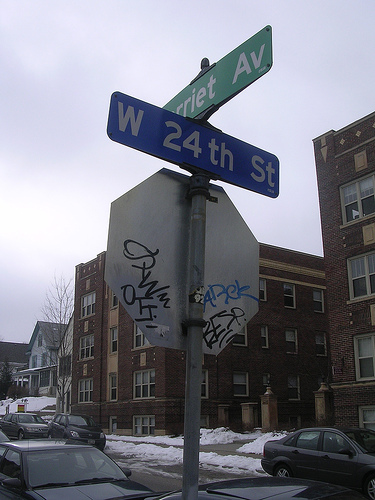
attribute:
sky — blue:
[23, 92, 78, 160]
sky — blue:
[18, 78, 81, 169]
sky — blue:
[36, 114, 94, 175]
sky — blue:
[25, 99, 90, 229]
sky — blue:
[306, 40, 359, 87]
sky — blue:
[70, 39, 149, 75]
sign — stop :
[101, 167, 279, 362]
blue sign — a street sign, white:
[103, 94, 292, 206]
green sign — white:
[172, 21, 302, 105]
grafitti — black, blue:
[114, 238, 257, 348]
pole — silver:
[168, 172, 222, 464]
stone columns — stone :
[303, 386, 339, 423]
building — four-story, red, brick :
[301, 112, 374, 445]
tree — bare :
[31, 266, 86, 415]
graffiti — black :
[110, 243, 267, 357]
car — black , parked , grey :
[245, 415, 372, 491]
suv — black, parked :
[49, 407, 110, 448]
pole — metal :
[174, 196, 227, 499]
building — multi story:
[70, 252, 332, 423]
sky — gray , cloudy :
[3, 4, 374, 154]